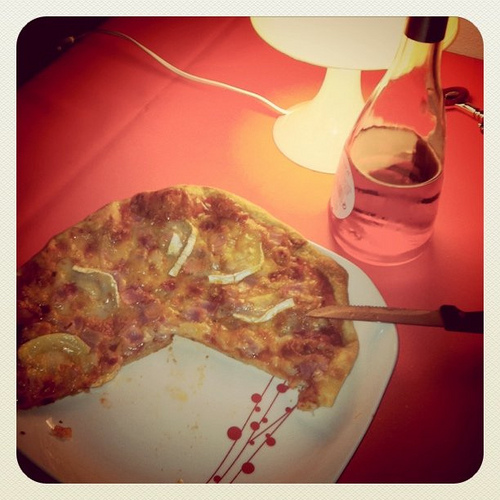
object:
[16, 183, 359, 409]
pizza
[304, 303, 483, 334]
knife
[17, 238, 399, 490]
plate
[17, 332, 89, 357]
topping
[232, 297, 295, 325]
topping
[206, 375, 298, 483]
flower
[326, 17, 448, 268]
bottle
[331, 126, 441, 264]
water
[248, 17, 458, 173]
lamp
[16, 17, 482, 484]
table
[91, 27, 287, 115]
cord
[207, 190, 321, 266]
crust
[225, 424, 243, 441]
dot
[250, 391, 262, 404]
dot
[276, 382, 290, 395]
dot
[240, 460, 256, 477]
dot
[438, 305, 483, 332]
handle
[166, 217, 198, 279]
topping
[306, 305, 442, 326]
blade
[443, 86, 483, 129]
key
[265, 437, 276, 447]
dot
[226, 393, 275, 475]
dots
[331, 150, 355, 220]
label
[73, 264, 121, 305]
topping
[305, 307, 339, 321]
tip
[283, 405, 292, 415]
dot